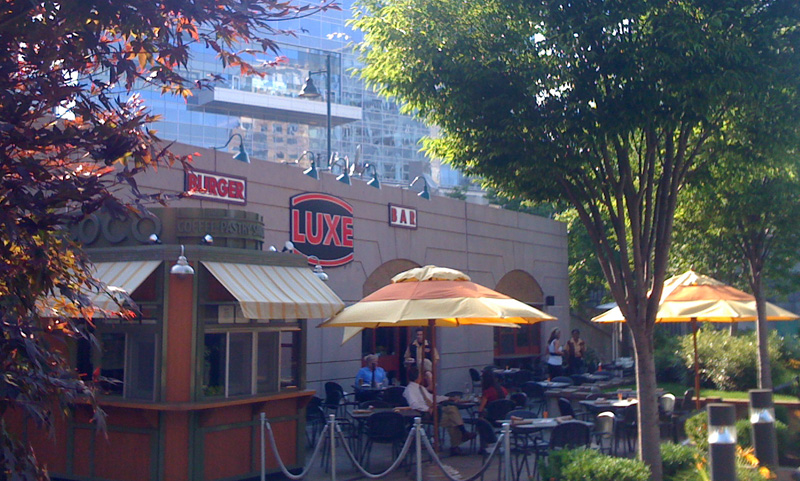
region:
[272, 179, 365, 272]
sign in middle reads luxe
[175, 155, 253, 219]
small sign on left reads burger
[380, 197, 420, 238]
sign on right reads bar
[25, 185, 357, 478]
small attachment in front of building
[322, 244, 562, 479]
umbrella in front of tables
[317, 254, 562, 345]
umbrella is yellow and orange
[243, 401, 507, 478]
rope along side patio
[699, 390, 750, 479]
light pole in front of tree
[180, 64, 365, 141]
square light above building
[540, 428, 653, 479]
small bush beside tree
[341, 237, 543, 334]
yellow and orange umbrella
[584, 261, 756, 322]
yellow and orange umbrella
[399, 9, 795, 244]
tall green trees by building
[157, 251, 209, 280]
building light on corner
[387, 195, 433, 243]
white and red bar sign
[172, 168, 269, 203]
white and red burger sign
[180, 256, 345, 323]
yellow and orange awning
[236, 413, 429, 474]
poles with rope by building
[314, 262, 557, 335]
yellow and orange market umbrella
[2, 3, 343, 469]
red and brown leaves on trees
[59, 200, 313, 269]
green roof on shack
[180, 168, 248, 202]
burger written in red letters on side of building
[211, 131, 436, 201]
row of blue overhead lights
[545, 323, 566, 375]
woman in white shirt and black skirt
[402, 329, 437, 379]
waiter in brown vest serving food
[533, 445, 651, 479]
small green bush next to tree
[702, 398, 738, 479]
metal and glass light fixtures on walkway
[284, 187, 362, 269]
LUXE written in red letters on building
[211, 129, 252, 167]
light hangs from roof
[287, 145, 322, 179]
light hangs from roof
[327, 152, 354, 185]
light hangs from roof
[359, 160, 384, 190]
light hangs from roof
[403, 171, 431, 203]
light hangs from roof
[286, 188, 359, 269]
sign is on side of building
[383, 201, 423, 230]
sign is on side of building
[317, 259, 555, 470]
umbrella is orange and yellow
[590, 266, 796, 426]
umbrella is orange and yellow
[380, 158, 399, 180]
A window on a building.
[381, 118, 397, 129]
A window on a building.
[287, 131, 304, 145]
A window on a building.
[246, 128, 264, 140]
A window on a building.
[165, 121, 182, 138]
A window on a building.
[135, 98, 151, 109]
A window on a building.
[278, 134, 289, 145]
A window on a building.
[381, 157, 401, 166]
A window on a building.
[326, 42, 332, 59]
A window on a building.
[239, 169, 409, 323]
sign on the building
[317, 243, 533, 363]
umbrella above the ground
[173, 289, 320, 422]
windows on the building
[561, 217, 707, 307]
branches of the tree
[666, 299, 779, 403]
bushes in distance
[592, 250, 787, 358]
orange and white umbrella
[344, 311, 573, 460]
people under the umbrella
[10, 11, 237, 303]
red leaves on the tree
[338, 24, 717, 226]
top part of tree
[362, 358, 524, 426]
the people are sitting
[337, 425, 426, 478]
the chain link is silver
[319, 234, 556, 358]
umbrella next to building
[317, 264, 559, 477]
the opened umbrella is yellow and orange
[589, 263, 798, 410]
the opened umbrella is yellow and orange